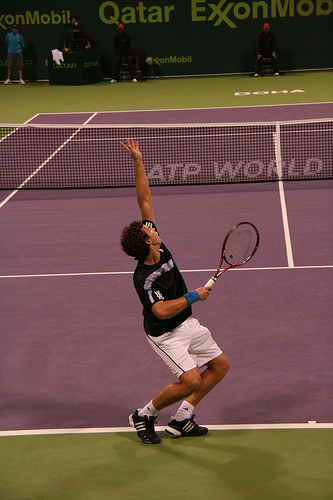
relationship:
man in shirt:
[3, 23, 24, 84] [4, 30, 26, 53]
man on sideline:
[5, 25, 26, 86] [2, 80, 255, 109]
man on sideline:
[109, 17, 138, 82] [3, 76, 236, 103]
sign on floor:
[230, 83, 306, 99] [0, 63, 328, 496]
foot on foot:
[129, 408, 161, 444] [127, 405, 160, 446]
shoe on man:
[163, 414, 208, 437] [120, 139, 229, 445]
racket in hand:
[203, 221, 259, 287] [195, 285, 212, 301]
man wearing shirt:
[120, 139, 229, 445] [132, 218, 191, 335]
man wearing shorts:
[120, 139, 229, 445] [142, 315, 220, 379]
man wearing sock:
[120, 139, 229, 445] [172, 399, 193, 420]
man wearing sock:
[120, 139, 229, 445] [137, 393, 156, 417]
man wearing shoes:
[120, 139, 229, 445] [124, 404, 212, 444]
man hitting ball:
[120, 139, 229, 445] [143, 53, 158, 66]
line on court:
[255, 116, 322, 282] [1, 105, 316, 442]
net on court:
[4, 116, 332, 197] [1, 105, 316, 442]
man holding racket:
[108, 132, 257, 443] [187, 220, 261, 297]